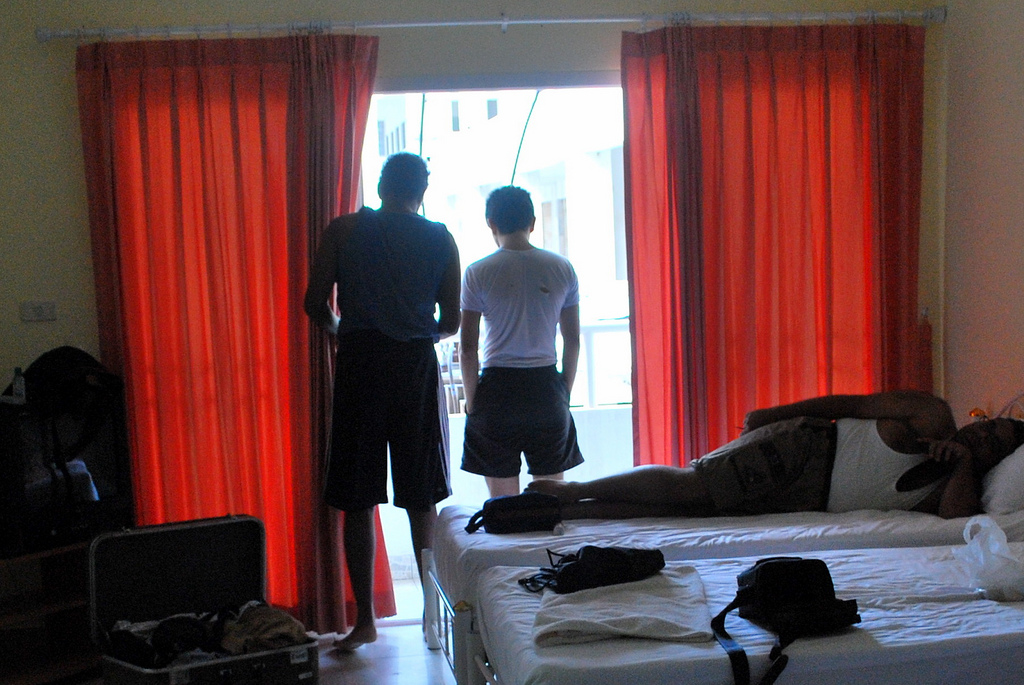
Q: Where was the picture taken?
A: In a bedroom.